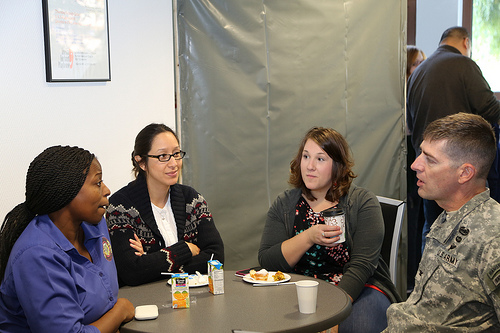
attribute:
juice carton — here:
[172, 275, 190, 308]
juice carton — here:
[208, 260, 224, 294]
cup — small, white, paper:
[296, 280, 319, 315]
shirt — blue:
[2, 216, 117, 331]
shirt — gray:
[259, 189, 400, 302]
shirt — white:
[152, 196, 178, 245]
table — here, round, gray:
[120, 269, 351, 331]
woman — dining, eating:
[259, 127, 402, 332]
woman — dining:
[106, 124, 223, 284]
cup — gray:
[324, 210, 347, 244]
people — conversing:
[1, 113, 499, 331]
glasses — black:
[149, 150, 187, 162]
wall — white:
[2, 1, 175, 221]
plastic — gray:
[173, 1, 409, 298]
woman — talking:
[3, 146, 136, 331]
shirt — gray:
[408, 45, 500, 157]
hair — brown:
[292, 127, 357, 201]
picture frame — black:
[44, 1, 113, 83]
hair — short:
[424, 113, 496, 180]